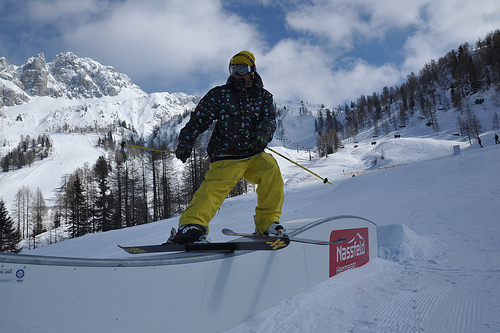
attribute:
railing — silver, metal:
[15, 229, 322, 284]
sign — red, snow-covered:
[328, 224, 370, 277]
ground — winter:
[375, 160, 413, 195]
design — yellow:
[267, 239, 287, 253]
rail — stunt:
[2, 184, 393, 331]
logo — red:
[325, 225, 375, 276]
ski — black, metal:
[114, 229, 306, 273]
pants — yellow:
[187, 155, 284, 242]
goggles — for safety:
[226, 57, 265, 81]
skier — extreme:
[168, 47, 293, 240]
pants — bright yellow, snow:
[181, 154, 283, 231]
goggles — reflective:
[227, 59, 257, 74]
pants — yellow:
[178, 149, 288, 228]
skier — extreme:
[165, 42, 299, 250]